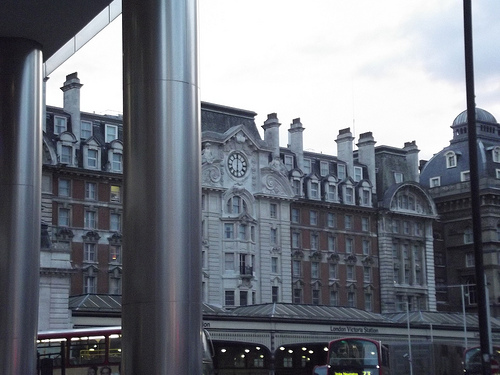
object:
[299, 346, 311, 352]
lights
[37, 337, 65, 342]
light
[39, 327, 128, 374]
bus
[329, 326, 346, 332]
london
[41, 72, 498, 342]
building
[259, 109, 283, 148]
chimney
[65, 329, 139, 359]
mirror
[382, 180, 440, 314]
archways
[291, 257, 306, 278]
windows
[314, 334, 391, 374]
bus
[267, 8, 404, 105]
clouds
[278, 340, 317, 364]
ceiling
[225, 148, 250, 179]
clock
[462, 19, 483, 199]
pole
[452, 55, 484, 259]
light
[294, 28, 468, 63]
sky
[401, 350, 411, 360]
lights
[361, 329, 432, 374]
entry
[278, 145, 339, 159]
roof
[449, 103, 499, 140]
dome